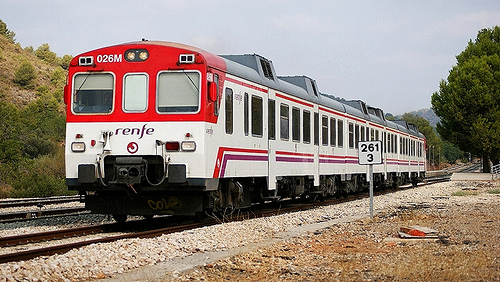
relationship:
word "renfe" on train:
[110, 121, 157, 142] [62, 37, 427, 226]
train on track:
[62, 37, 427, 226] [3, 215, 206, 266]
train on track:
[67, 43, 433, 182] [0, 169, 456, 259]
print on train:
[95, 52, 121, 62] [53, 22, 447, 236]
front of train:
[58, 39, 213, 219] [53, 22, 447, 236]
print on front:
[95, 52, 121, 62] [58, 39, 213, 219]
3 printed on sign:
[364, 149, 378, 161] [357, 140, 382, 164]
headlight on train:
[178, 140, 198, 153] [62, 37, 427, 226]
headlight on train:
[68, 139, 91, 153] [62, 37, 427, 226]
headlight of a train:
[180, 140, 196, 151] [62, 37, 427, 226]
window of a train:
[152, 68, 202, 117] [62, 37, 427, 226]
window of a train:
[130, 80, 245, 118] [29, 33, 374, 258]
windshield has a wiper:
[76, 68, 113, 118] [73, 68, 97, 98]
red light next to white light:
[163, 137, 182, 152] [179, 136, 197, 153]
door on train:
[268, 91, 275, 192] [62, 37, 427, 226]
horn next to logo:
[96, 127, 118, 158] [111, 114, 162, 140]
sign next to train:
[356, 137, 384, 167] [62, 37, 427, 226]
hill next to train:
[0, 17, 83, 198] [50, 22, 485, 233]